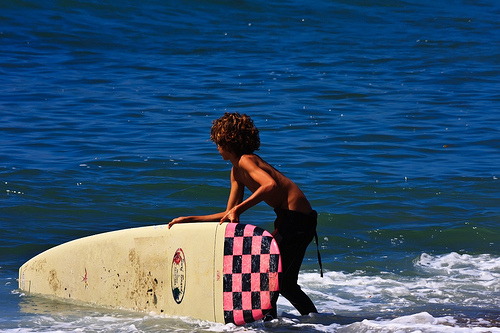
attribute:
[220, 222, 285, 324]
pattern — pink, black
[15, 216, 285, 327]
surfboard — pink and black, checkered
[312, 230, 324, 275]
drawstring — black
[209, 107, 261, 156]
hair — wavy, brown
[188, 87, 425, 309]
boy — bending, anxious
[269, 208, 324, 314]
pants — black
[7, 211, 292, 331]
surf board — yellow, black, pink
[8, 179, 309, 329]
surfboard — on its side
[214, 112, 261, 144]
curly hair — brown curly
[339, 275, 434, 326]
froth — white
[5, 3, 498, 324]
water — blue, ocean, shallow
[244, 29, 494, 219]
water — dark, blue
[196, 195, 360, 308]
pants — black, draw stringed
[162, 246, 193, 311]
logo — round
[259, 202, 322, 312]
pants — black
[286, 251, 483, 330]
foam — white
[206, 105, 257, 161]
head — boy's, back